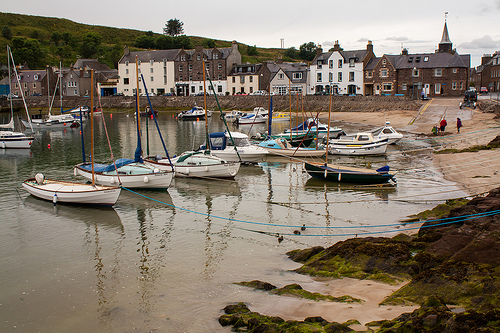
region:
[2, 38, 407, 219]
several boats anchored in water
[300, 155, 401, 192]
blue boat anchored near beach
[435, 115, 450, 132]
person in red shirt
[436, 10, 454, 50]
spire atop distant building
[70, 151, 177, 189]
white boat with blue tarp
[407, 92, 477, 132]
boat ramp near buildings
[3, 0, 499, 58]
the clouds in the sky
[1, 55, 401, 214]
the boats in the water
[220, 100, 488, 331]
the riverbank shore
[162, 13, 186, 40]
tree on the hill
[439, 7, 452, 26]
the steeple on top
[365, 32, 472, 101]
the brick houses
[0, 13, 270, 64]
the hill in the horizon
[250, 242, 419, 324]
the muddy waters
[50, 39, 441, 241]
this is a bay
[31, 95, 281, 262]
these are boats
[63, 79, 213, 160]
the pole are wooden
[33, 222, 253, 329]
the water is brown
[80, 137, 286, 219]
the boats are white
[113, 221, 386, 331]
the water is clear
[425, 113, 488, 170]
the beach is sandy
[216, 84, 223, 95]
a window on a building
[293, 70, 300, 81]
a window on a building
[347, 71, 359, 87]
a window on a building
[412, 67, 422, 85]
a window on a building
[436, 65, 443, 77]
a window on a building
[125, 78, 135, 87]
a window on a building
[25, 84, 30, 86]
a window on a building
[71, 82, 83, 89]
a window on a building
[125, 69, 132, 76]
a window on a building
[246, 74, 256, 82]
a window on a building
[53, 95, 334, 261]
this is a bay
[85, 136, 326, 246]
these are a bunch of sailboats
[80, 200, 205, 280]
the water is brown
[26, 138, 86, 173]
the water is green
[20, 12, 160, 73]
the hills are green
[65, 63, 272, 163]
the poles are wooden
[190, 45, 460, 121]
these are old houses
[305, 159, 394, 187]
The boat is green.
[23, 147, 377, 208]
Boats are in a row.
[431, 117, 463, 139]
People are on the shore.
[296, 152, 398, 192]
The boat is in water.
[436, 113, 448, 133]
a person wearing a red coat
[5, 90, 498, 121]
a rock retaining wall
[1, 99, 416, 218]
a group of boats i the water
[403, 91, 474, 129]
a ramp to get to the beach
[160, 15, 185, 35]
a tree standing on top of the hill by itself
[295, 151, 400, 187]
the black boat that is closest to the camera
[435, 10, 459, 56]
a tall steeple on a building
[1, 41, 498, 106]
a long row of buildings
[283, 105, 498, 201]
a sandy shoreline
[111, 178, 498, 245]
a blue rope that ties the front-most boat to the shore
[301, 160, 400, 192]
black boat in water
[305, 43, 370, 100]
white building in distance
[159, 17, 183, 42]
tree on ledge in distance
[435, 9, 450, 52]
tower of building in distance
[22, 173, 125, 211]
white boat closest to camera